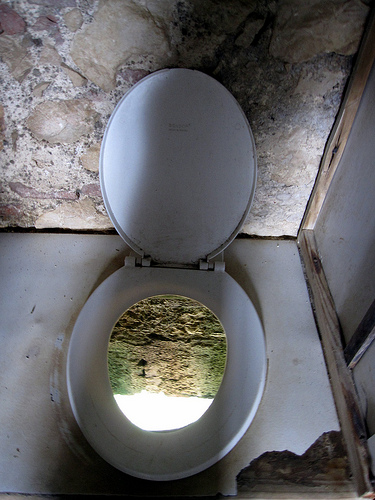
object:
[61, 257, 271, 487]
seat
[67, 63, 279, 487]
toilet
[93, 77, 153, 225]
reflection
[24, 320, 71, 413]
surface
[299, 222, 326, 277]
frame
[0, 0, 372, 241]
wall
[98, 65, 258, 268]
cover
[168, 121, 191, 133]
name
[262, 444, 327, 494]
crack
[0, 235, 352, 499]
floor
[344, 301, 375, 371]
plank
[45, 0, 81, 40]
rock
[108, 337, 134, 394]
plant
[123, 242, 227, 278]
step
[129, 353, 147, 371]
knot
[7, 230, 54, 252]
space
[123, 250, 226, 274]
stone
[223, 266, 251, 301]
edge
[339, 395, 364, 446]
wood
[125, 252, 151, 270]
hinge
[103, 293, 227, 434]
portal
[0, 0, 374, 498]
bathroom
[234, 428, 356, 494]
board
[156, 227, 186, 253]
dirt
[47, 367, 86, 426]
paint